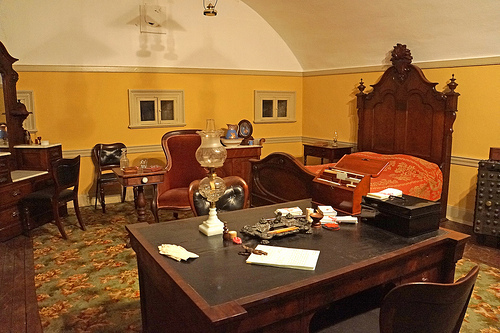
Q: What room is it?
A: It is a bedroom.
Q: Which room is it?
A: It is a bedroom.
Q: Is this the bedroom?
A: Yes, it is the bedroom.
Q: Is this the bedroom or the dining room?
A: It is the bedroom.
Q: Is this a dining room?
A: No, it is a bedroom.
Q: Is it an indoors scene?
A: Yes, it is indoors.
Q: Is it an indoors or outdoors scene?
A: It is indoors.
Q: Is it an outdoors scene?
A: No, it is indoors.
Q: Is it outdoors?
A: No, it is indoors.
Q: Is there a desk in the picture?
A: Yes, there is a desk.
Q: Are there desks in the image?
A: Yes, there is a desk.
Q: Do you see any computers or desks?
A: Yes, there is a desk.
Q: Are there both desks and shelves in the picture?
A: No, there is a desk but no shelves.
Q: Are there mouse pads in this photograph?
A: No, there are no mouse pads.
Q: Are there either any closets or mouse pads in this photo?
A: No, there are no mouse pads or closets.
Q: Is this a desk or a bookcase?
A: This is a desk.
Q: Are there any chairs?
A: Yes, there is a chair.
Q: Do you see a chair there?
A: Yes, there is a chair.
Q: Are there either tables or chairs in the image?
A: Yes, there is a chair.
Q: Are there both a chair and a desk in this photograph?
A: Yes, there are both a chair and a desk.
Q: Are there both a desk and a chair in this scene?
A: Yes, there are both a chair and a desk.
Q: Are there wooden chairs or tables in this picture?
A: Yes, there is a wood chair.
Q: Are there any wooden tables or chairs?
A: Yes, there is a wood chair.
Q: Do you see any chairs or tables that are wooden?
A: Yes, the chair is wooden.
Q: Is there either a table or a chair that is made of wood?
A: Yes, the chair is made of wood.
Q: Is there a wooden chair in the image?
A: Yes, there is a wood chair.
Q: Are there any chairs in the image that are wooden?
A: Yes, there is a chair that is wooden.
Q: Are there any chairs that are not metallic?
A: Yes, there is a wooden chair.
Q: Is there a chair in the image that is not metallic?
A: Yes, there is a wooden chair.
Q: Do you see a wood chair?
A: Yes, there is a chair that is made of wood.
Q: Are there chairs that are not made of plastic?
A: Yes, there is a chair that is made of wood.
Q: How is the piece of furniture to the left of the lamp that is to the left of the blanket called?
A: The piece of furniture is a chair.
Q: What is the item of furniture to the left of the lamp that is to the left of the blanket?
A: The piece of furniture is a chair.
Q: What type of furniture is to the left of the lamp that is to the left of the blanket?
A: The piece of furniture is a chair.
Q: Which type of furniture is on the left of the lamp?
A: The piece of furniture is a chair.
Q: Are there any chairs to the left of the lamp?
A: Yes, there is a chair to the left of the lamp.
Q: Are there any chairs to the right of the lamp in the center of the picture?
A: No, the chair is to the left of the lamp.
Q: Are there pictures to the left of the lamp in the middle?
A: No, there is a chair to the left of the lamp.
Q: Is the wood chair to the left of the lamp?
A: Yes, the chair is to the left of the lamp.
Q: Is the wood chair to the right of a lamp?
A: No, the chair is to the left of a lamp.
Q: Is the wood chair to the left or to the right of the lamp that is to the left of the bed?
A: The chair is to the left of the lamp.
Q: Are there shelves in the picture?
A: No, there are no shelves.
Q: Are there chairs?
A: Yes, there is a chair.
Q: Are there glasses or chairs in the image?
A: Yes, there is a chair.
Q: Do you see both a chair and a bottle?
A: No, there is a chair but no bottles.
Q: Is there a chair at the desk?
A: Yes, there is a chair at the desk.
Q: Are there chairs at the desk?
A: Yes, there is a chair at the desk.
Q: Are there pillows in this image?
A: No, there are no pillows.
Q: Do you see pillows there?
A: No, there are no pillows.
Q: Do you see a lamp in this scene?
A: Yes, there is a lamp.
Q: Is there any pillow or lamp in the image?
A: Yes, there is a lamp.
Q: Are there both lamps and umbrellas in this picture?
A: No, there is a lamp but no umbrellas.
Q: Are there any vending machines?
A: No, there are no vending machines.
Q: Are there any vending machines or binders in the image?
A: No, there are no vending machines or binders.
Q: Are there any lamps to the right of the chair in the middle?
A: Yes, there is a lamp to the right of the chair.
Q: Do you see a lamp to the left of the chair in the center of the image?
A: No, the lamp is to the right of the chair.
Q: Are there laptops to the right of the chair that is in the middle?
A: No, there is a lamp to the right of the chair.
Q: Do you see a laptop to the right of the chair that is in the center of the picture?
A: No, there is a lamp to the right of the chair.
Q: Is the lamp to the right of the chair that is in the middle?
A: Yes, the lamp is to the right of the chair.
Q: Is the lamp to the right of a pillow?
A: No, the lamp is to the right of the chair.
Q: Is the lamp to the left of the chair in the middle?
A: No, the lamp is to the right of the chair.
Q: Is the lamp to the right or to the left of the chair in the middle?
A: The lamp is to the right of the chair.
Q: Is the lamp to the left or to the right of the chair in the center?
A: The lamp is to the right of the chair.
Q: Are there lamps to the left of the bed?
A: Yes, there is a lamp to the left of the bed.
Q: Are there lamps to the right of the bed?
A: No, the lamp is to the left of the bed.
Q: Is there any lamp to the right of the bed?
A: No, the lamp is to the left of the bed.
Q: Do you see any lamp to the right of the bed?
A: No, the lamp is to the left of the bed.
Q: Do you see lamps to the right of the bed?
A: No, the lamp is to the left of the bed.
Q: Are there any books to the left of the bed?
A: No, there is a lamp to the left of the bed.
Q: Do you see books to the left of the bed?
A: No, there is a lamp to the left of the bed.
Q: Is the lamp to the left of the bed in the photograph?
A: Yes, the lamp is to the left of the bed.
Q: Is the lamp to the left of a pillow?
A: No, the lamp is to the left of the bed.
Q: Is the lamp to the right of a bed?
A: No, the lamp is to the left of a bed.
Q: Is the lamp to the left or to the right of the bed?
A: The lamp is to the left of the bed.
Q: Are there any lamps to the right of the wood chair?
A: Yes, there is a lamp to the right of the chair.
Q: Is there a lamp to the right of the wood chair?
A: Yes, there is a lamp to the right of the chair.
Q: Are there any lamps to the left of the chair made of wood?
A: No, the lamp is to the right of the chair.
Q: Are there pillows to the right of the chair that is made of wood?
A: No, there is a lamp to the right of the chair.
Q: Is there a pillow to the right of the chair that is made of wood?
A: No, there is a lamp to the right of the chair.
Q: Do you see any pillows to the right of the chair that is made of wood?
A: No, there is a lamp to the right of the chair.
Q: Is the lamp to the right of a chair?
A: Yes, the lamp is to the right of a chair.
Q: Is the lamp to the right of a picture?
A: No, the lamp is to the right of a chair.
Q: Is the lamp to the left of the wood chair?
A: No, the lamp is to the right of the chair.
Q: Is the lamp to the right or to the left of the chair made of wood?
A: The lamp is to the right of the chair.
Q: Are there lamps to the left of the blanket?
A: Yes, there is a lamp to the left of the blanket.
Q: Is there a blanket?
A: Yes, there is a blanket.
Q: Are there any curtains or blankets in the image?
A: Yes, there is a blanket.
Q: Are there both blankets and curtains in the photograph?
A: No, there is a blanket but no curtains.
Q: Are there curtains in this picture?
A: No, there are no curtains.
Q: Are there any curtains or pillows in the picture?
A: No, there are no curtains or pillows.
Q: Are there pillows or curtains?
A: No, there are no curtains or pillows.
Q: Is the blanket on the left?
A: No, the blanket is on the right of the image.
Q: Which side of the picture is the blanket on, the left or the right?
A: The blanket is on the right of the image.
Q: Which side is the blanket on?
A: The blanket is on the right of the image.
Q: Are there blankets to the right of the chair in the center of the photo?
A: Yes, there is a blanket to the right of the chair.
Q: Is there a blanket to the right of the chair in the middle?
A: Yes, there is a blanket to the right of the chair.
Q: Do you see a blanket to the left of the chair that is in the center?
A: No, the blanket is to the right of the chair.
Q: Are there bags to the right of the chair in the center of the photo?
A: No, there is a blanket to the right of the chair.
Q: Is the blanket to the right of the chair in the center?
A: Yes, the blanket is to the right of the chair.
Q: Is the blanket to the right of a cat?
A: No, the blanket is to the right of the chair.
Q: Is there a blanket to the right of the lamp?
A: Yes, there is a blanket to the right of the lamp.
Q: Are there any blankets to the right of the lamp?
A: Yes, there is a blanket to the right of the lamp.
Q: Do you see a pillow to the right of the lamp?
A: No, there is a blanket to the right of the lamp.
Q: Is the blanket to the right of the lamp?
A: Yes, the blanket is to the right of the lamp.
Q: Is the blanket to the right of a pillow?
A: No, the blanket is to the right of the lamp.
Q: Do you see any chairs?
A: Yes, there is a chair.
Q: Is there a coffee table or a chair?
A: Yes, there is a chair.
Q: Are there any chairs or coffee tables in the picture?
A: Yes, there is a chair.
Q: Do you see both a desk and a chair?
A: Yes, there are both a chair and a desk.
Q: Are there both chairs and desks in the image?
A: Yes, there are both a chair and a desk.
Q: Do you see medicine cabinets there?
A: No, there are no medicine cabinets.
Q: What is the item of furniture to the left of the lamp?
A: The piece of furniture is a chair.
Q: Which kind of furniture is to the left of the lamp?
A: The piece of furniture is a chair.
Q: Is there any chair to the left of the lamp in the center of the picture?
A: Yes, there is a chair to the left of the lamp.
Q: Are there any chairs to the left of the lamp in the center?
A: Yes, there is a chair to the left of the lamp.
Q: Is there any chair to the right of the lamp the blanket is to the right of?
A: No, the chair is to the left of the lamp.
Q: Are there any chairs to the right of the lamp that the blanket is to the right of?
A: No, the chair is to the left of the lamp.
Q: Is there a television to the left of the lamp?
A: No, there is a chair to the left of the lamp.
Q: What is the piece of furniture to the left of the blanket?
A: The piece of furniture is a chair.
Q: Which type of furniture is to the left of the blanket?
A: The piece of furniture is a chair.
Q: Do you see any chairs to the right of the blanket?
A: No, the chair is to the left of the blanket.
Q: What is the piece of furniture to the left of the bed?
A: The piece of furniture is a chair.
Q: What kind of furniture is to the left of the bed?
A: The piece of furniture is a chair.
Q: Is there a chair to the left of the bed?
A: Yes, there is a chair to the left of the bed.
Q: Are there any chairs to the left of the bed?
A: Yes, there is a chair to the left of the bed.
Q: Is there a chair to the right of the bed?
A: No, the chair is to the left of the bed.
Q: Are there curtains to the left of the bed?
A: No, there is a chair to the left of the bed.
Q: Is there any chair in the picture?
A: Yes, there is a chair.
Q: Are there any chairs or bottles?
A: Yes, there is a chair.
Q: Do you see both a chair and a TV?
A: No, there is a chair but no televisions.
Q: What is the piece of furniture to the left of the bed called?
A: The piece of furniture is a chair.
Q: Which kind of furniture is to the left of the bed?
A: The piece of furniture is a chair.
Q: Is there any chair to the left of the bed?
A: Yes, there is a chair to the left of the bed.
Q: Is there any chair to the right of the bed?
A: No, the chair is to the left of the bed.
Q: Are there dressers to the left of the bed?
A: No, there is a chair to the left of the bed.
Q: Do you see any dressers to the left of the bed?
A: No, there is a chair to the left of the bed.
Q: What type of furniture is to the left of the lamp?
A: The piece of furniture is a chair.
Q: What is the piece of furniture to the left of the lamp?
A: The piece of furniture is a chair.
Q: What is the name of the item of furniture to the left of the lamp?
A: The piece of furniture is a chair.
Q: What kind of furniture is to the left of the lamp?
A: The piece of furniture is a chair.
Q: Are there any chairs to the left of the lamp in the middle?
A: Yes, there is a chair to the left of the lamp.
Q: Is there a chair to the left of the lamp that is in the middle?
A: Yes, there is a chair to the left of the lamp.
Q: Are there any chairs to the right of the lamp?
A: No, the chair is to the left of the lamp.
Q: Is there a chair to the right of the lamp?
A: No, the chair is to the left of the lamp.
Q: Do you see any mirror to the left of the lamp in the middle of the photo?
A: No, there is a chair to the left of the lamp.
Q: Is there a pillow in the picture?
A: No, there are no pillows.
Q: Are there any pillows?
A: No, there are no pillows.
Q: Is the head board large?
A: Yes, the head board is large.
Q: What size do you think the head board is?
A: The head board is large.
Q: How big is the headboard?
A: The headboard is large.